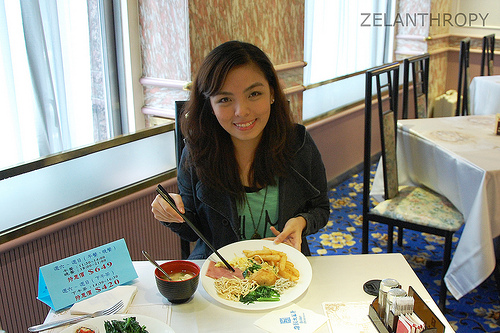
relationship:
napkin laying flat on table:
[263, 304, 325, 331] [7, 236, 468, 331]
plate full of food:
[198, 237, 312, 312] [206, 259, 243, 279]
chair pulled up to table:
[481, 34, 495, 75] [463, 75, 499, 115]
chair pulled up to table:
[454, 37, 471, 115] [463, 75, 499, 115]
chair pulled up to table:
[402, 53, 429, 123] [463, 75, 499, 115]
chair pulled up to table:
[362, 64, 464, 311] [463, 75, 499, 115]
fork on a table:
[24, 298, 124, 331] [36, 251, 455, 331]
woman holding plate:
[132, 31, 329, 264] [198, 237, 312, 312]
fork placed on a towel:
[24, 298, 124, 331] [70, 283, 137, 316]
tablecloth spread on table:
[369, 112, 499, 301] [370, 112, 499, 304]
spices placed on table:
[377, 276, 424, 331] [36, 251, 455, 331]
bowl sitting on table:
[156, 259, 200, 304] [36, 251, 455, 331]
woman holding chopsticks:
[132, 31, 329, 264] [158, 181, 235, 271]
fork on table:
[24, 298, 124, 331] [36, 251, 455, 331]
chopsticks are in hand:
[153, 185, 234, 273] [151, 190, 186, 225]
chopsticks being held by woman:
[153, 185, 234, 273] [148, 42, 330, 254]